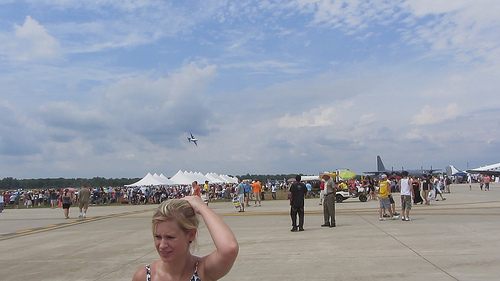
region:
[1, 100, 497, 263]
people at an air show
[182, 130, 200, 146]
an airplane in the air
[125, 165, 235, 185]
a group of white tents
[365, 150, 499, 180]
planes on the ground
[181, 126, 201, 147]
a plane in the air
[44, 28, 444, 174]
clouds in the sky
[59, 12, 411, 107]
blue sky amongst the clouds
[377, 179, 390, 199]
a man in a yellow shirt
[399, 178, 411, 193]
a man in a white shirt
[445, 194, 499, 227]
lines in the concrete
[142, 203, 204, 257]
head of a person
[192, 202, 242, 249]
arm of a person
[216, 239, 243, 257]
elbow of a person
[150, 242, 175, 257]
nose of a person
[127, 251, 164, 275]
shoulder of a person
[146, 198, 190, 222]
hair of a person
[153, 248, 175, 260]
mouth of a person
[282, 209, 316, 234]
leg of a person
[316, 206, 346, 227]
leg of a person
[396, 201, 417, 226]
leg of a person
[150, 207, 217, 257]
the head of a woman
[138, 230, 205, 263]
the eyes of a woman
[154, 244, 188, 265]
the mouth of a woman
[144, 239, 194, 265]
the chin of a woman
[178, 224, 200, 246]
the ears of a woman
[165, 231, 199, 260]
the cheek of a woman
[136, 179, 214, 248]
the hair of a woman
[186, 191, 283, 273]
the arm of a woman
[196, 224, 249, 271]
the elbow of a woman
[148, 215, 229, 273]
the neck of a woman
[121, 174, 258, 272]
woman wearing black and white top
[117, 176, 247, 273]
woman has hand on her hair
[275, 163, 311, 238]
man wearing black shirt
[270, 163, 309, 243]
man wearing black jeans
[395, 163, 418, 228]
man wearing white tank top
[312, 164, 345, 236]
man wearing cowboy hat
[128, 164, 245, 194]
white cone tents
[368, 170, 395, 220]
man wearing yellow tank top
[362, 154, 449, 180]
gray airplane parked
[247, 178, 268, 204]
man wearing orange shirt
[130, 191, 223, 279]
white woman wearing a strappy shirt in the foreground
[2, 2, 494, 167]
overcast sky with patches of blue sky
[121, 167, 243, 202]
numerous event tents with white canopies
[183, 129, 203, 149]
airplane doing tricks in the air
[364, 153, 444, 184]
gray plane on the landing strip for display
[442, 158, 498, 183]
white plane on landing strip on display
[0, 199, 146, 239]
runway markings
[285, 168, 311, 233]
man in the distance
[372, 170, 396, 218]
man wearing yellow shirt and gray shorts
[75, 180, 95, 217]
man wearing khaki-colored outfit